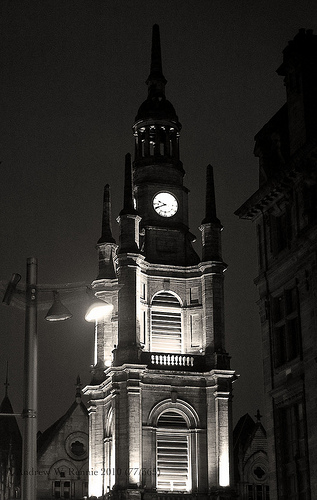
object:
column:
[200, 275, 215, 355]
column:
[143, 130, 151, 161]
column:
[121, 151, 134, 210]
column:
[204, 161, 218, 221]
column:
[100, 181, 112, 240]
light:
[84, 290, 113, 323]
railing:
[145, 350, 204, 371]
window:
[148, 287, 183, 309]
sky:
[0, 0, 289, 432]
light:
[152, 190, 180, 220]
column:
[135, 127, 141, 158]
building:
[233, 24, 316, 498]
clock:
[151, 188, 179, 218]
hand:
[153, 204, 166, 210]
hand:
[157, 200, 164, 206]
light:
[43, 293, 73, 325]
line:
[31, 279, 88, 289]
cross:
[253, 408, 263, 422]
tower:
[80, 19, 242, 499]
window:
[62, 477, 74, 491]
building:
[35, 372, 90, 499]